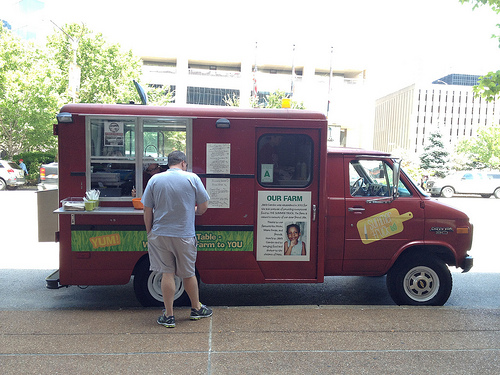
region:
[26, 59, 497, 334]
a red food truck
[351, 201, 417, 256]
a yellow sign stylized as a cutting board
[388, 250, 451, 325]
a tire on a vehicle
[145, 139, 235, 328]
a man ordering lunch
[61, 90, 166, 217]
a window into a mobile kitchen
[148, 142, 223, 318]
a man wearing a grey tshirt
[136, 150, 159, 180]
a food truck worker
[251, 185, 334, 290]
a sign reviewing food source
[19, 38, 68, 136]
a tree lit by the sun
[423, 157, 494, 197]
a white car parked on the street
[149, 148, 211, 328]
THIS IS A PERSON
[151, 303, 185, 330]
THAT IS A SHOE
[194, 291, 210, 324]
THAT IS A SHOE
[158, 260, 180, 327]
THAT IS A LEG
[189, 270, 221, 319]
THAT IS A LEG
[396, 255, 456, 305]
THAT IS A WHEEL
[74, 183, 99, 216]
THAT IS A PLATE OF FOOD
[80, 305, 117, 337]
THIS IS THE GROUND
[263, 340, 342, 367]
THIS IS THE GROUND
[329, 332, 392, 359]
THIS IS THE GROUND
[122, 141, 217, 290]
man stands at truck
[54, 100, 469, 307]
red food truck on street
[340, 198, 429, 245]
yellow logo on truck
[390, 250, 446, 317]
truck has black wheels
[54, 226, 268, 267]
green sign on truck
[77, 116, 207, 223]
grey frame on window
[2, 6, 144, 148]
green trees behind truck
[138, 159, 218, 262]
man has grey shirt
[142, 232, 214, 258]
man has grey pants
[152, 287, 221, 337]
black and white shoes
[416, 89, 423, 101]
glass window on building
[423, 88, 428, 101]
glass window on building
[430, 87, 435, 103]
glass window on building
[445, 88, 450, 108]
glass window on building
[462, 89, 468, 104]
glass window on building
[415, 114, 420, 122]
glass window on building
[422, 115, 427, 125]
glass window on building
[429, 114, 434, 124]
glass window on building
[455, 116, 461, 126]
glass window on building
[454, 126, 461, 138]
glass window on building